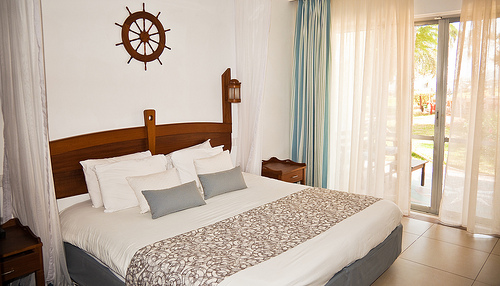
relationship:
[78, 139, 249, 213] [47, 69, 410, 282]
pillows of bed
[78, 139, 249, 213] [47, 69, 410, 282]
pillows over bed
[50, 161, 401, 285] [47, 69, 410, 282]
cover over bed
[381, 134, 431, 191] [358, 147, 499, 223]
chair at patio